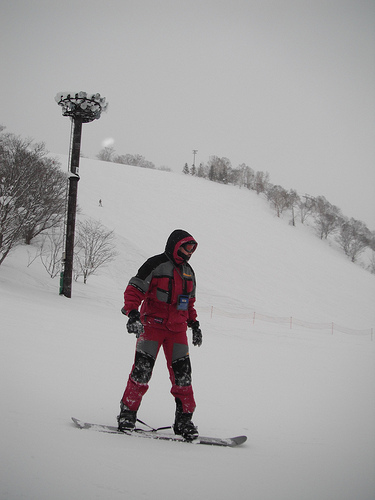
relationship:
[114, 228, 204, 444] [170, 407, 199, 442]
man wearing boots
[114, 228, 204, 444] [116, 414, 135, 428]
man wearing shoe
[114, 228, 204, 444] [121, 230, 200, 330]
man wearing coat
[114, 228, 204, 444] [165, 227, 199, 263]
man has head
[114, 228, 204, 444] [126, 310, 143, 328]
man has hand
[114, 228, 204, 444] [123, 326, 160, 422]
man has leg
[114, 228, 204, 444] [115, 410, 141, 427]
man has foot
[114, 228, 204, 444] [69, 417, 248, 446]
man on skiboard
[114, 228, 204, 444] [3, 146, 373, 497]
man in snow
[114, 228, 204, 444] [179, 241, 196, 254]
man wearing goggles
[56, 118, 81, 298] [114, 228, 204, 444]
pole near man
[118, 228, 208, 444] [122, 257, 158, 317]
man has arm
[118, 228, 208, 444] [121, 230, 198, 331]
man wears coat